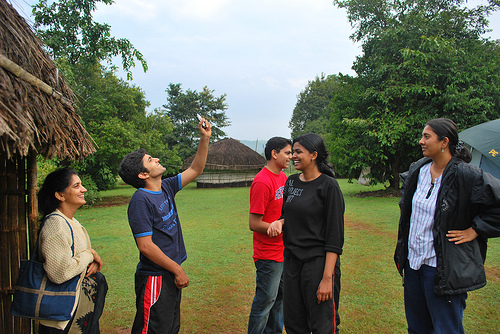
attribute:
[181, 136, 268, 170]
grass hut — thatched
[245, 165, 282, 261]
shirt — red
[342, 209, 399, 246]
path — foot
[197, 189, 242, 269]
grass — green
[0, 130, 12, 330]
pole — wooden